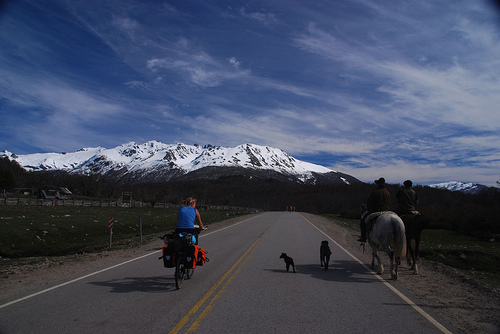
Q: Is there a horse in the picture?
A: Yes, there are horses.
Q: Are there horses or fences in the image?
A: Yes, there are horses.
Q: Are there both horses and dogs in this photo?
A: Yes, there are both horses and a dog.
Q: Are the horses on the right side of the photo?
A: Yes, the horses are on the right of the image.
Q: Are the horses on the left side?
A: No, the horses are on the right of the image.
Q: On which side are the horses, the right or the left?
A: The horses are on the right of the image.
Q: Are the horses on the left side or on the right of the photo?
A: The horses are on the right of the image.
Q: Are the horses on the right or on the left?
A: The horses are on the right of the image.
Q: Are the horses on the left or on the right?
A: The horses are on the right of the image.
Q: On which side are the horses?
A: The horses are on the right of the image.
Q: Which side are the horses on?
A: The horses are on the right of the image.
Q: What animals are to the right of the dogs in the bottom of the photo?
A: The animals are horses.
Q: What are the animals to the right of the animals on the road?
A: The animals are horses.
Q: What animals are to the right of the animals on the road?
A: The animals are horses.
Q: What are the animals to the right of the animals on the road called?
A: The animals are horses.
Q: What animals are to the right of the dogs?
A: The animals are horses.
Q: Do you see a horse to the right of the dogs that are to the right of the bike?
A: Yes, there are horses to the right of the dogs.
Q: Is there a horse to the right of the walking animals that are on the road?
A: Yes, there are horses to the right of the dogs.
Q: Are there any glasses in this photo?
A: No, there are no glasses.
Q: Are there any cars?
A: No, there are no cars.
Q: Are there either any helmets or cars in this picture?
A: No, there are no cars or helmets.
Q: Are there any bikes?
A: Yes, there is a bike.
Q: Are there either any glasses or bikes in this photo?
A: Yes, there is a bike.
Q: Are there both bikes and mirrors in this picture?
A: No, there is a bike but no mirrors.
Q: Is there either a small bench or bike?
A: Yes, there is a small bike.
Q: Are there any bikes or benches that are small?
A: Yes, the bike is small.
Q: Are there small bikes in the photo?
A: Yes, there is a small bike.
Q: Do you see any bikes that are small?
A: Yes, there is a bike that is small.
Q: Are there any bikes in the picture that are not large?
A: Yes, there is a small bike.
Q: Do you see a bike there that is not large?
A: Yes, there is a small bike.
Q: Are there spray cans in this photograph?
A: No, there are no spray cans.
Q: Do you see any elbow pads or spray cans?
A: No, there are no spray cans or elbow pads.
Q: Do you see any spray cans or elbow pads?
A: No, there are no spray cans or elbow pads.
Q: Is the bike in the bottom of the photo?
A: Yes, the bike is in the bottom of the image.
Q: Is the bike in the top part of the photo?
A: No, the bike is in the bottom of the image.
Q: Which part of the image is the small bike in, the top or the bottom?
A: The bike is in the bottom of the image.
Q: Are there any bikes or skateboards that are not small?
A: No, there is a bike but it is small.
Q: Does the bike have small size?
A: Yes, the bike is small.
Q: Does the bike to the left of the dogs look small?
A: Yes, the bike is small.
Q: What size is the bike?
A: The bike is small.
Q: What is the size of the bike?
A: The bike is small.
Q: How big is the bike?
A: The bike is small.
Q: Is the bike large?
A: No, the bike is small.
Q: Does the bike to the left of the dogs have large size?
A: No, the bike is small.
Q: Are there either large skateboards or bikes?
A: No, there is a bike but it is small.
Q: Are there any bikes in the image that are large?
A: No, there is a bike but it is small.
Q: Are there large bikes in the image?
A: No, there is a bike but it is small.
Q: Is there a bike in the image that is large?
A: No, there is a bike but it is small.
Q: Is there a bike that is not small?
A: No, there is a bike but it is small.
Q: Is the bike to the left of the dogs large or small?
A: The bike is small.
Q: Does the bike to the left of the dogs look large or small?
A: The bike is small.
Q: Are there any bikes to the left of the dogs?
A: Yes, there is a bike to the left of the dogs.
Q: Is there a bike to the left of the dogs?
A: Yes, there is a bike to the left of the dogs.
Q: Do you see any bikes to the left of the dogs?
A: Yes, there is a bike to the left of the dogs.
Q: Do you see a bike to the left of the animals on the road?
A: Yes, there is a bike to the left of the dogs.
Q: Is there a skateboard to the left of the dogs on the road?
A: No, there is a bike to the left of the dogs.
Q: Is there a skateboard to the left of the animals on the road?
A: No, there is a bike to the left of the dogs.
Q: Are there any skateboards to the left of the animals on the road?
A: No, there is a bike to the left of the dogs.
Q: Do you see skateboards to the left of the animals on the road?
A: No, there is a bike to the left of the dogs.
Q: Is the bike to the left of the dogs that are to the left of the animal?
A: Yes, the bike is to the left of the dogs.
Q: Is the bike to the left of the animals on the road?
A: Yes, the bike is to the left of the dogs.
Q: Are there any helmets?
A: No, there are no helmets.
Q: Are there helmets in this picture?
A: No, there are no helmets.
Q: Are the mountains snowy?
A: Yes, the mountains are snowy.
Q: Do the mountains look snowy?
A: Yes, the mountains are snowy.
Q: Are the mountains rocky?
A: No, the mountains are snowy.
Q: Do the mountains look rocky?
A: No, the mountains are snowy.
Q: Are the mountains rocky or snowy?
A: The mountains are snowy.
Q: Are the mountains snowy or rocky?
A: The mountains are snowy.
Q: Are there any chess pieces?
A: No, there are no chess pieces.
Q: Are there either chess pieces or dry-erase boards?
A: No, there are no chess pieces or dry-erase boards.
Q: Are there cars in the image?
A: No, there are no cars.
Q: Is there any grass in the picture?
A: Yes, there is grass.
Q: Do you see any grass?
A: Yes, there is grass.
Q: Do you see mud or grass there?
A: Yes, there is grass.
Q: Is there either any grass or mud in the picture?
A: Yes, there is grass.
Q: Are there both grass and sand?
A: No, there is grass but no sand.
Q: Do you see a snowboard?
A: No, there are no snowboards.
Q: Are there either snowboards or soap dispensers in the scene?
A: No, there are no snowboards or soap dispensers.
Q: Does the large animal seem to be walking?
A: Yes, the animal is walking.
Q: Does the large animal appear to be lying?
A: No, the animal is walking.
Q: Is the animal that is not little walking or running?
A: The animal is walking.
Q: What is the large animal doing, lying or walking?
A: The animal is walking.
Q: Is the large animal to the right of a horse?
A: Yes, the animal is to the right of a horse.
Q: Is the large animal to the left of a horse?
A: No, the animal is to the right of a horse.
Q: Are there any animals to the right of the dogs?
A: Yes, there is an animal to the right of the dogs.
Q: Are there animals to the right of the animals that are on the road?
A: Yes, there is an animal to the right of the dogs.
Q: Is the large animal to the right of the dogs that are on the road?
A: Yes, the animal is to the right of the dogs.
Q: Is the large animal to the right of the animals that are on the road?
A: Yes, the animal is to the right of the dogs.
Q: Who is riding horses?
A: The people are riding horses.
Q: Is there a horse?
A: Yes, there is a horse.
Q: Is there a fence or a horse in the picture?
A: Yes, there is a horse.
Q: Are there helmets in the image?
A: No, there are no helmets.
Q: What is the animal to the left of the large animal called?
A: The animal is a horse.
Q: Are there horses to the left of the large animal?
A: Yes, there is a horse to the left of the animal.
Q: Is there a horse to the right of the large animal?
A: No, the horse is to the left of the animal.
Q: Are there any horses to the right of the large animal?
A: No, the horse is to the left of the animal.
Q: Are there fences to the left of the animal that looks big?
A: No, there is a horse to the left of the animal.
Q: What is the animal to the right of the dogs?
A: The animal is a horse.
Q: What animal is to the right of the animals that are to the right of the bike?
A: The animal is a horse.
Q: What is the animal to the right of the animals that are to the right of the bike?
A: The animal is a horse.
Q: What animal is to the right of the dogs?
A: The animal is a horse.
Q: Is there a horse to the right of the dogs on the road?
A: Yes, there is a horse to the right of the dogs.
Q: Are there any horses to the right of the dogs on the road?
A: Yes, there is a horse to the right of the dogs.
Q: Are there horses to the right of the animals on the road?
A: Yes, there is a horse to the right of the dogs.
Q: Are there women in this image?
A: Yes, there is a woman.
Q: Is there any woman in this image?
A: Yes, there is a woman.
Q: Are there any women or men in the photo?
A: Yes, there is a woman.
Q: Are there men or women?
A: Yes, there is a woman.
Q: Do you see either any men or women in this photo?
A: Yes, there is a woman.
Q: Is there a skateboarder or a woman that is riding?
A: Yes, the woman is riding.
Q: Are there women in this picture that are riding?
A: Yes, there is a woman that is riding.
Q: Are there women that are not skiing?
A: Yes, there is a woman that is riding.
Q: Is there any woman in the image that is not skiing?
A: Yes, there is a woman that is riding.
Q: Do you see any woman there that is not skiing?
A: Yes, there is a woman that is riding .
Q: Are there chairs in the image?
A: No, there are no chairs.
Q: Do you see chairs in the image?
A: No, there are no chairs.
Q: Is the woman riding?
A: Yes, the woman is riding.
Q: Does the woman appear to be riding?
A: Yes, the woman is riding.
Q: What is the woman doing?
A: The woman is riding.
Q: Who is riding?
A: The woman is riding.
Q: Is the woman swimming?
A: No, the woman is riding.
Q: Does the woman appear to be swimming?
A: No, the woman is riding.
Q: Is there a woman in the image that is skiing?
A: No, there is a woman but she is riding.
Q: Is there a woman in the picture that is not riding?
A: No, there is a woman but she is riding.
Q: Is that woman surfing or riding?
A: The woman is riding.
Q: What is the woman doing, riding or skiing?
A: The woman is riding.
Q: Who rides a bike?
A: The woman rides a bike.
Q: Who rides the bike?
A: The woman rides a bike.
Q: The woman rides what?
A: The woman rides a bike.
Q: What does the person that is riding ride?
A: The woman rides a bike.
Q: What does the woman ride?
A: The woman rides a bike.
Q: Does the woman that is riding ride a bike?
A: Yes, the woman rides a bike.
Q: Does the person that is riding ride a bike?
A: Yes, the woman rides a bike.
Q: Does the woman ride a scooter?
A: No, the woman rides a bike.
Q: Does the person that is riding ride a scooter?
A: No, the woman rides a bike.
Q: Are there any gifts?
A: No, there are no gifts.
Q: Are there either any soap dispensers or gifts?
A: No, there are no gifts or soap dispensers.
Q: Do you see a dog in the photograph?
A: Yes, there are dogs.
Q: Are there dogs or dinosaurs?
A: Yes, there are dogs.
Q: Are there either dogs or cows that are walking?
A: Yes, the dogs are walking.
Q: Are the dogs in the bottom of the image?
A: Yes, the dogs are in the bottom of the image.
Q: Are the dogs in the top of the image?
A: No, the dogs are in the bottom of the image.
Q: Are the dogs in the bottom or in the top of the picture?
A: The dogs are in the bottom of the image.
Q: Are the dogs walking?
A: Yes, the dogs are walking.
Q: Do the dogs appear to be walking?
A: Yes, the dogs are walking.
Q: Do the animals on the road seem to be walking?
A: Yes, the dogs are walking.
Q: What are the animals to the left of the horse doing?
A: The dogs are walking.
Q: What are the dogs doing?
A: The dogs are walking.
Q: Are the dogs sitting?
A: No, the dogs are walking.